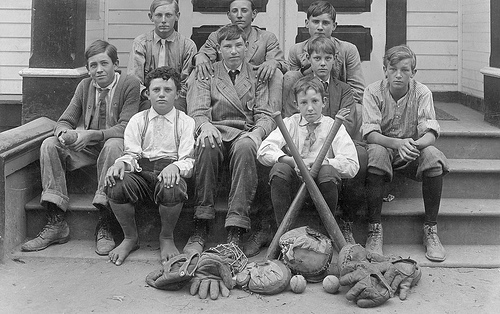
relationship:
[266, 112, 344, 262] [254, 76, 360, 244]
baseball bat in front of boy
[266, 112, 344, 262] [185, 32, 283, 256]
baseball bat in front of boy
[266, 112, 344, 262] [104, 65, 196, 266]
baseball bat in front of boy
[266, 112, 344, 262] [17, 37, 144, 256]
baseball bat in front of kid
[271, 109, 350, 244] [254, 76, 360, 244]
baseball bat in front of boy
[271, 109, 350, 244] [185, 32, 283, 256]
baseball bat in front of boy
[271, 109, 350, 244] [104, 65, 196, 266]
baseball bat in front of boy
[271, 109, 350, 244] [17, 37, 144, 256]
baseball bat in front of kid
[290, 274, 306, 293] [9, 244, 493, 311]
ball on ground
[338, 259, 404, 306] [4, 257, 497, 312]
glove on ground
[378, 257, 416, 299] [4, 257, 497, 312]
glove on ground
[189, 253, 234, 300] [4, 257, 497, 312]
glove on ground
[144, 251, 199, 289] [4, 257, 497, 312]
glove on ground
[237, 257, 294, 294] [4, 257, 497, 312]
glove on ground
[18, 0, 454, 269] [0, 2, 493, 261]
boys sitting in front of building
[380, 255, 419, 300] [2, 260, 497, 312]
glove on floor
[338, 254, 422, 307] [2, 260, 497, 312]
glove on floor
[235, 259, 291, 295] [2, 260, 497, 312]
glove on floor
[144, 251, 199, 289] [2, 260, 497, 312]
glove on floor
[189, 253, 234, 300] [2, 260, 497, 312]
glove on floor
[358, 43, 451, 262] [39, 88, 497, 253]
boy sitting on steps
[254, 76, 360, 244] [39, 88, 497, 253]
boy sitting on steps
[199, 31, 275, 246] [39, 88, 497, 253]
boy sitting on steps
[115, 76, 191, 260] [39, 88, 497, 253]
boy sitting on steps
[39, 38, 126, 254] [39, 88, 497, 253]
boy sitting on steps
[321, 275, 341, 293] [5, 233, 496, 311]
ball on ground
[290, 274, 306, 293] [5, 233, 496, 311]
ball on ground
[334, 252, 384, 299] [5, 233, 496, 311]
glove on ground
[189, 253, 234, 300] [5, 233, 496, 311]
glove on ground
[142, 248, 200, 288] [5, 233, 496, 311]
glove on ground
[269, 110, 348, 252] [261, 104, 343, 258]
baseball bat crisscrossed with bat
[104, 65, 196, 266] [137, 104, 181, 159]
boy wearing suspenders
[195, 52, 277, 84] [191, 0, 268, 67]
hands of boy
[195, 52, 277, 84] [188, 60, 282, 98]
hands on shoulders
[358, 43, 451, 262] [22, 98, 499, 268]
boy on steps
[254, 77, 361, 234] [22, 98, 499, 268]
boy on steps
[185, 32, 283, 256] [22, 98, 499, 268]
boy on steps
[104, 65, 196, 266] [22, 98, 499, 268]
boy on steps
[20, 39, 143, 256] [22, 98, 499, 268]
boy on steps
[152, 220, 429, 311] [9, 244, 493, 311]
gear on ground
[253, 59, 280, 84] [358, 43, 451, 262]
hand on boy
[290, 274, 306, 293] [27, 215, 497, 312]
ball on ground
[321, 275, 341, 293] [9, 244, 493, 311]
ball on ground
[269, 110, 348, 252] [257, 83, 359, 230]
baseball bat in front of boy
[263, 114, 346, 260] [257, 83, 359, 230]
baseball bat in front of boy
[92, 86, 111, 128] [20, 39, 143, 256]
tie on boy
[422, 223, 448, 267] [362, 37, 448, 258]
shoe on boy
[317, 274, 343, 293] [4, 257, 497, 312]
ball on ground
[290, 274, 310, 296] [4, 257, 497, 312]
ball on ground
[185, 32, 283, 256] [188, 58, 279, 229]
boy wearing suit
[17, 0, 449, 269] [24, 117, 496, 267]
group sitting on steps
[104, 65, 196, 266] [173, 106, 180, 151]
boy wearing suspender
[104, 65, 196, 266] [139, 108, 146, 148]
boy wearing suspender